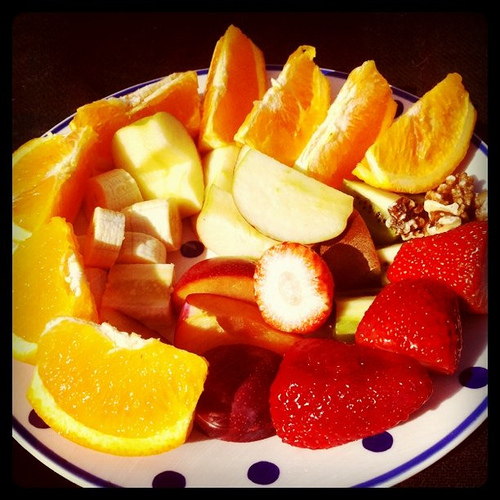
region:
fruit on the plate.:
[7, 20, 492, 458]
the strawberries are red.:
[265, 214, 485, 449]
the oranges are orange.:
[7, 127, 210, 446]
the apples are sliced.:
[112, 109, 357, 256]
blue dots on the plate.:
[147, 362, 492, 489]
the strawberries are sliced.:
[267, 214, 492, 449]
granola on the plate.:
[392, 169, 480, 240]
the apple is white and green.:
[231, 145, 356, 240]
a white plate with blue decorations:
[13, 61, 491, 488]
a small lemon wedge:
[31, 311, 207, 464]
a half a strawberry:
[265, 335, 430, 450]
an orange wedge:
[197, 25, 265, 147]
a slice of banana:
[81, 205, 128, 265]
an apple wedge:
[230, 141, 357, 238]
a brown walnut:
[430, 170, 482, 215]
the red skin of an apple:
[193, 343, 279, 443]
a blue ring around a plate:
[12, 394, 486, 492]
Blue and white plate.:
[14, 23, 491, 498]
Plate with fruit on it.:
[16, 25, 491, 491]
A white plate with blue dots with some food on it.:
[12, 17, 484, 492]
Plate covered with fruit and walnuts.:
[10, 18, 485, 496]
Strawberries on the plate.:
[255, 220, 495, 441]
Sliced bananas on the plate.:
[85, 166, 176, 271]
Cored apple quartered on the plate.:
[115, 112, 391, 269]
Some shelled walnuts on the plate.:
[390, 172, 490, 233]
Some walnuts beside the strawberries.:
[393, 172, 483, 237]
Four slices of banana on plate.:
[82, 162, 185, 264]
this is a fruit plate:
[25, 61, 430, 496]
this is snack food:
[54, 167, 431, 479]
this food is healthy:
[49, 174, 420, 416]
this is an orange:
[47, 278, 222, 488]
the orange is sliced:
[37, 324, 229, 489]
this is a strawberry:
[267, 337, 425, 457]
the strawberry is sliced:
[277, 335, 432, 470]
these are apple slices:
[190, 153, 366, 350]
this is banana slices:
[100, 181, 165, 321]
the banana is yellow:
[115, 240, 187, 316]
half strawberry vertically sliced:
[268, 335, 433, 450]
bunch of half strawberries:
[270, 220, 490, 450]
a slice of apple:
[228, 137, 358, 242]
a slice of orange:
[28, 314, 212, 458]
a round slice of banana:
[78, 203, 125, 268]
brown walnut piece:
[419, 165, 483, 224]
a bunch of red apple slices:
[105, 112, 360, 467]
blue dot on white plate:
[243, 457, 283, 486]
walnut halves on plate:
[381, 170, 498, 247]